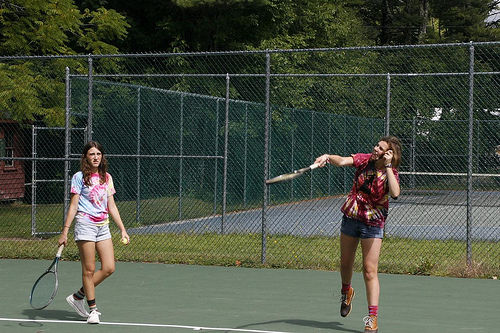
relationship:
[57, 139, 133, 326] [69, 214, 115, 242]
partner wearing shorts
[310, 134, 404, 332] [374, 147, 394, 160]
lady on phone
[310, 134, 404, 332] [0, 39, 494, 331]
lady playing on tennis court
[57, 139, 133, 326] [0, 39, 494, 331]
partner playing on tennis court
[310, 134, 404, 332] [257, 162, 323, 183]
lady holding tennis racket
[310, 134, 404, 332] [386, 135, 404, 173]
lady has hair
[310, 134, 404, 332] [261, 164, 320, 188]
lady swinging tennis racket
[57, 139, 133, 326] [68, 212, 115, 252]
partner wearing shorts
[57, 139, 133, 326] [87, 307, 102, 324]
partner wearing white shoe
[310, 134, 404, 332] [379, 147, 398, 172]
lady talking on cell phone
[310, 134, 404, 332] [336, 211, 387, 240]
lady wearing colored shorts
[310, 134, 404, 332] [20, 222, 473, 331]
lady playing game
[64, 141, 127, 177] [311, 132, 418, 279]
head of woman